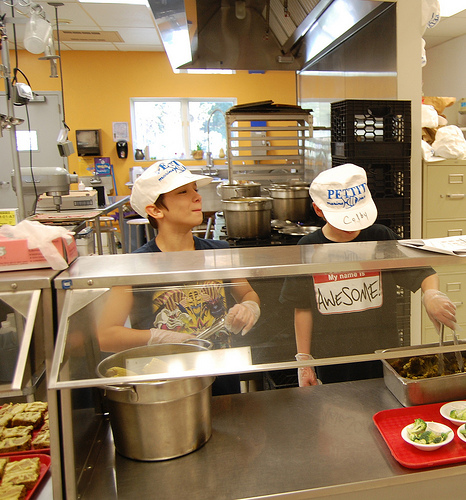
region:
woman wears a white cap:
[121, 147, 226, 264]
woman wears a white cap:
[298, 156, 396, 274]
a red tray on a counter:
[372, 391, 464, 471]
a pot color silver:
[90, 330, 225, 473]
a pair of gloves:
[146, 296, 265, 347]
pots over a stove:
[212, 170, 309, 240]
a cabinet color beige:
[419, 152, 464, 352]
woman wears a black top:
[261, 161, 457, 379]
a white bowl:
[393, 408, 454, 450]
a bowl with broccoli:
[395, 408, 455, 454]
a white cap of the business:
[309, 163, 376, 228]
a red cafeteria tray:
[373, 402, 465, 467]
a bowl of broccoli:
[402, 420, 453, 451]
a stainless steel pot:
[96, 342, 212, 459]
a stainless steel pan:
[381, 345, 464, 404]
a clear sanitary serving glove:
[222, 300, 270, 337]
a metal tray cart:
[224, 101, 313, 188]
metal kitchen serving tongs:
[438, 323, 464, 377]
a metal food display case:
[56, 237, 464, 498]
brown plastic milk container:
[330, 98, 411, 163]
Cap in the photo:
[309, 171, 377, 224]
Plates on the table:
[390, 395, 463, 456]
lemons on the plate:
[412, 417, 445, 445]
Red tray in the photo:
[364, 414, 399, 475]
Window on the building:
[151, 109, 218, 152]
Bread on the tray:
[5, 408, 51, 452]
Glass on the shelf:
[204, 300, 327, 344]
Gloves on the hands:
[163, 304, 265, 347]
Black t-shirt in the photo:
[284, 236, 437, 329]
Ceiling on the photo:
[85, 17, 124, 45]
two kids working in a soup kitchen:
[108, 140, 428, 411]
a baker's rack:
[219, 98, 338, 195]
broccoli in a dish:
[403, 409, 452, 454]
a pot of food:
[62, 326, 256, 461]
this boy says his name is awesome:
[303, 277, 406, 326]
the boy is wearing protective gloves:
[120, 306, 276, 358]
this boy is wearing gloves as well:
[404, 287, 465, 336]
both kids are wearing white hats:
[128, 157, 407, 234]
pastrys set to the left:
[0, 398, 54, 499]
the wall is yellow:
[82, 70, 120, 115]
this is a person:
[117, 151, 246, 372]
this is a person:
[286, 160, 455, 399]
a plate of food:
[387, 397, 451, 474]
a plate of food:
[437, 393, 464, 422]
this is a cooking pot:
[78, 339, 239, 460]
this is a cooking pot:
[216, 180, 275, 237]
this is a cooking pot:
[264, 158, 315, 240]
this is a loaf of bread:
[5, 405, 44, 440]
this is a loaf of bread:
[17, 388, 56, 414]